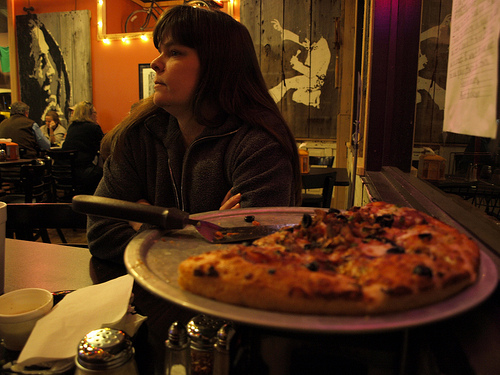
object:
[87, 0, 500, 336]
woman pizza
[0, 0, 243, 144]
orange wall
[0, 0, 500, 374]
restaurant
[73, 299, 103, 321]
paper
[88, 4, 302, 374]
lady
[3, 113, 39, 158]
vest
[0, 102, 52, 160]
man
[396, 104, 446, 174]
wall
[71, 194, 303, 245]
pie server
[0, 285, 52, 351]
cup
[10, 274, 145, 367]
napkin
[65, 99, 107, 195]
woman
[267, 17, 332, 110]
elvis drawing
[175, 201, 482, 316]
arch design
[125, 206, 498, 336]
pan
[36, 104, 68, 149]
woman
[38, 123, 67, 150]
jacket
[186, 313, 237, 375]
pepper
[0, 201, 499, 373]
table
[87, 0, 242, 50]
lights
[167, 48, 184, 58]
eye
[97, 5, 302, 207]
hair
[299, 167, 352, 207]
table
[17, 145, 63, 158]
table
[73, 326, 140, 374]
salt shaker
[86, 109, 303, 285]
coat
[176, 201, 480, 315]
pizza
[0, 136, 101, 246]
chair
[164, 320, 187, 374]
salt shaker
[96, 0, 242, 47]
art work